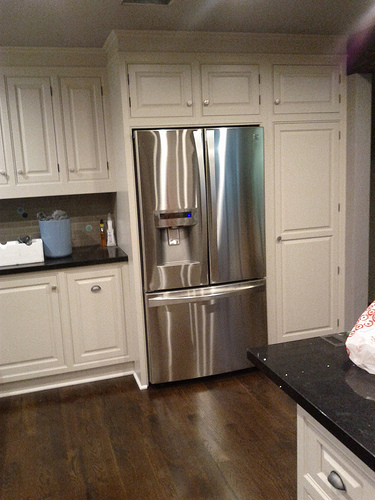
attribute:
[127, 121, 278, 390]
fridge — silver, steel, stainless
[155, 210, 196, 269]
dispenser — ice cube, digital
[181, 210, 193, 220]
light — blue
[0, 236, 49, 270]
container — styrofoam, white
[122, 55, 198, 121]
cupboard — white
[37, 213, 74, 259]
container — blue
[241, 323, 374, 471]
countertop — black, gray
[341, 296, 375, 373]
bag — plastic, white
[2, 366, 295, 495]
floors — laminated, brown, wooden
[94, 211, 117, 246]
bottles — sitting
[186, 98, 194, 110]
handle — metal, steel, gray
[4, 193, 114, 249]
backsplash — white, brown, brick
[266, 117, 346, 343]
cabinet — tall